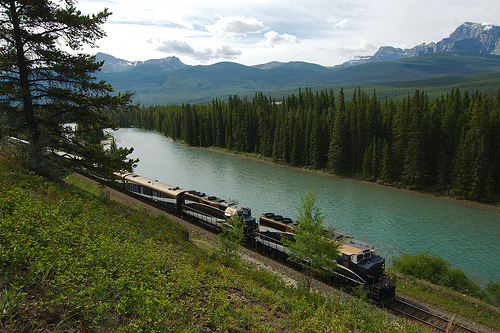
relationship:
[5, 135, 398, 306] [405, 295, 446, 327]
train on track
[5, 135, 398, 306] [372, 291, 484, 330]
train on tracks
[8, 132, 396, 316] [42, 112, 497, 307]
train along river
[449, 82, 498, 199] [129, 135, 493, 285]
trees along river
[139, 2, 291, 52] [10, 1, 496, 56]
clouds in sky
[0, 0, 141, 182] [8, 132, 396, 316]
tree above train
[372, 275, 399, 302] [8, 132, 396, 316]
handrail on train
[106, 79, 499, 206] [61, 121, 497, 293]
trees along river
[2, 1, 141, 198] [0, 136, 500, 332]
tree on hill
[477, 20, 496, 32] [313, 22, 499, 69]
snow on mountain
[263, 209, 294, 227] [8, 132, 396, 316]
black holes on train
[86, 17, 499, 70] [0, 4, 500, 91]
mountains in horizon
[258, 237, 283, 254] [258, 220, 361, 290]
white mark on side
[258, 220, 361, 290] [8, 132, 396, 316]
side of train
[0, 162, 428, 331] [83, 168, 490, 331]
grassy land near tracks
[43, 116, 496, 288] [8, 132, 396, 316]
water below train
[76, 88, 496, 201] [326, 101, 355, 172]
forest of tree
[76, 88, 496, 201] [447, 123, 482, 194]
forest of tree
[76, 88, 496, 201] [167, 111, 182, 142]
forest of tree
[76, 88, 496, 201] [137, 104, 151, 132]
forest of tree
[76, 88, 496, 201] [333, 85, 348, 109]
forest of tree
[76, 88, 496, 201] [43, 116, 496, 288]
forest across from water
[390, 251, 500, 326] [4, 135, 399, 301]
brush to side of train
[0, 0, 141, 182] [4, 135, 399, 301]
tree above train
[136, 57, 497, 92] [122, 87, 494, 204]
land behind trees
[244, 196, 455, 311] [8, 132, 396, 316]
car on end of train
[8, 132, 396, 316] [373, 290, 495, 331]
train on tracks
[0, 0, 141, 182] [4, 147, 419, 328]
tree on hill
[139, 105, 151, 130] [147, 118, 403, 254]
evergreen line water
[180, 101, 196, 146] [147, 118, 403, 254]
evergreen line water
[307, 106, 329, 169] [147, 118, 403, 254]
evergreen line water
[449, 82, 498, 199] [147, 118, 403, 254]
trees line water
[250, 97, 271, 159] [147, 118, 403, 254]
evergreen line water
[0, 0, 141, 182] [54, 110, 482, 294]
tree overlooking river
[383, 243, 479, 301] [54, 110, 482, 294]
brush along side of river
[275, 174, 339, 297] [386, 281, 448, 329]
tree near tracks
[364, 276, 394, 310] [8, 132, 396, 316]
steps to train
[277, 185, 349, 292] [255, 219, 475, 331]
tree by tracks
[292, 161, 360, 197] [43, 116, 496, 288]
ripples in water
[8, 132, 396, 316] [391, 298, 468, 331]
train on track